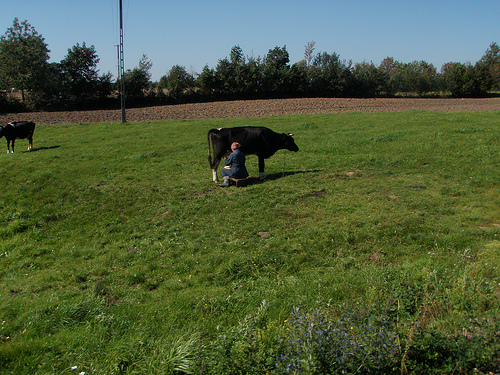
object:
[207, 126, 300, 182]
cow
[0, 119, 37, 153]
cow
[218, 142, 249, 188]
person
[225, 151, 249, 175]
jacket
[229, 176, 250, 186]
stool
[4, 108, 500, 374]
grass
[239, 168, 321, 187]
shadow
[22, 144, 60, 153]
shadow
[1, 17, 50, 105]
tree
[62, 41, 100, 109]
tree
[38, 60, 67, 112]
tree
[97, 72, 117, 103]
tree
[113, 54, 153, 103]
tree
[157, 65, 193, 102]
tree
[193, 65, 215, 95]
tree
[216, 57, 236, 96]
tree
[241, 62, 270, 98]
tree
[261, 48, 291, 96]
tree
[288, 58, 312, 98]
tree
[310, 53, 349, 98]
tree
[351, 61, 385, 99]
tree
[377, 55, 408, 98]
tree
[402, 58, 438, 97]
tree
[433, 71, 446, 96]
tree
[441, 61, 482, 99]
tree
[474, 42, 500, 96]
tree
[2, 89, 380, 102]
fence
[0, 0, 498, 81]
sky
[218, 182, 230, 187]
feet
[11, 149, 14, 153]
feet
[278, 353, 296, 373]
flowers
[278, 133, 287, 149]
neck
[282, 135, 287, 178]
rope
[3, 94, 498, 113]
soil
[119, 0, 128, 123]
tower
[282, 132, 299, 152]
head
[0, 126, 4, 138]
head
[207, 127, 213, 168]
tail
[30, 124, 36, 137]
tail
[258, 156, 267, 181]
legs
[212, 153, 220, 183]
legs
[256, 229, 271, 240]
spot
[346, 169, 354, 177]
spot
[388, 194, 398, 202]
spot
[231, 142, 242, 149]
hat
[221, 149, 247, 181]
clothing